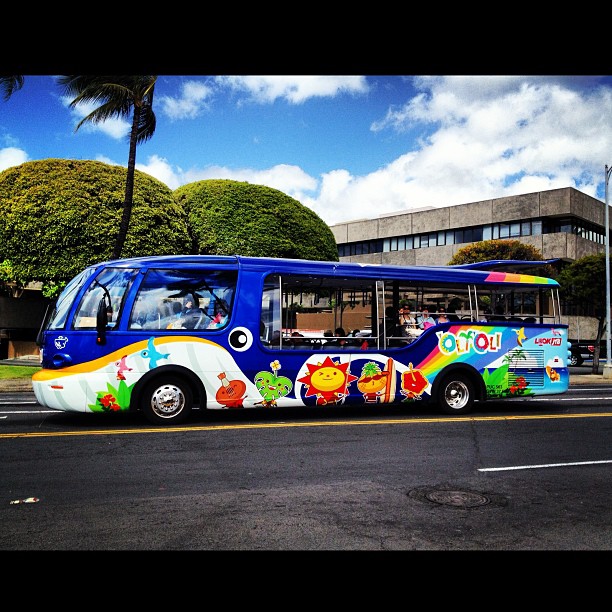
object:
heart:
[254, 371, 293, 404]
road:
[0, 389, 612, 553]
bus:
[31, 255, 569, 424]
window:
[445, 230, 455, 245]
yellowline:
[0, 413, 612, 440]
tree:
[0, 163, 196, 302]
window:
[492, 225, 499, 240]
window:
[499, 224, 510, 239]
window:
[509, 221, 520, 237]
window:
[521, 221, 531, 236]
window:
[531, 221, 542, 236]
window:
[473, 226, 483, 241]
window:
[437, 231, 446, 245]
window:
[429, 233, 437, 246]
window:
[413, 235, 420, 249]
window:
[383, 239, 390, 252]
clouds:
[0, 74, 611, 227]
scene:
[444, 326, 569, 395]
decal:
[297, 356, 358, 406]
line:
[477, 459, 612, 473]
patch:
[406, 482, 507, 507]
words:
[435, 331, 503, 356]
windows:
[280, 274, 380, 352]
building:
[322, 186, 611, 344]